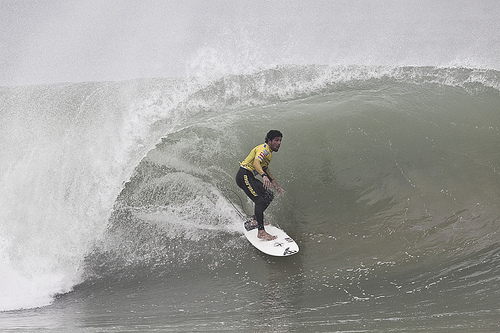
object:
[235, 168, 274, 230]
pants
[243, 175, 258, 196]
lettering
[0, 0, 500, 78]
sky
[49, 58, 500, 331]
ocean wave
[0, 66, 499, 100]
edge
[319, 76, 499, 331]
water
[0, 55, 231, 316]
foam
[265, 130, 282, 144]
hair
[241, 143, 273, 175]
shirt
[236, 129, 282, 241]
man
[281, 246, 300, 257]
nose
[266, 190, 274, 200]
knee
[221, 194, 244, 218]
string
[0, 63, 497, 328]
ocean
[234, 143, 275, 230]
body suit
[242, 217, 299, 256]
board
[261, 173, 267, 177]
watch